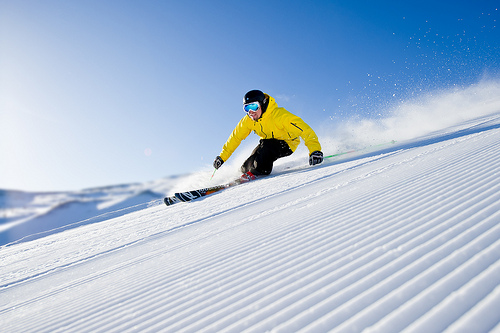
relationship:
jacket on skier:
[217, 96, 321, 153] [210, 89, 322, 184]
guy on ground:
[211, 89, 323, 182] [0, 110, 499, 332]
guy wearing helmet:
[213, 89, 323, 184] [240, 89, 267, 111]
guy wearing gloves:
[211, 89, 323, 182] [208, 152, 328, 169]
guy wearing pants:
[211, 89, 323, 182] [220, 127, 289, 201]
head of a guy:
[237, 87, 273, 120] [211, 89, 323, 182]